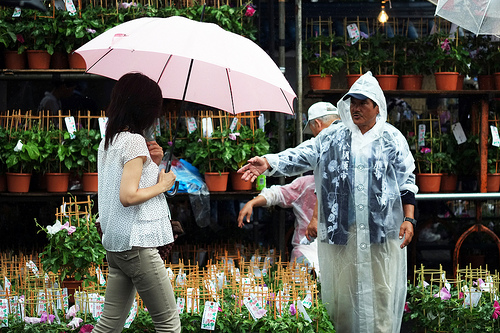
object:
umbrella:
[69, 12, 304, 199]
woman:
[91, 67, 189, 331]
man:
[234, 67, 420, 332]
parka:
[261, 69, 418, 332]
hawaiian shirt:
[266, 124, 419, 243]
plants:
[40, 221, 93, 292]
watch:
[401, 216, 420, 227]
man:
[299, 98, 339, 139]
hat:
[301, 101, 338, 135]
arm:
[265, 126, 336, 172]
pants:
[86, 241, 181, 332]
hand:
[236, 154, 270, 184]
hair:
[103, 69, 165, 150]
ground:
[7, 331, 496, 332]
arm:
[120, 133, 161, 209]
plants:
[302, 14, 342, 91]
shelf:
[302, 86, 499, 100]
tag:
[346, 22, 362, 44]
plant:
[340, 16, 373, 79]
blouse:
[92, 127, 175, 251]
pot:
[344, 72, 365, 89]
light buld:
[377, 7, 389, 26]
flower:
[439, 37, 452, 53]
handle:
[163, 159, 180, 198]